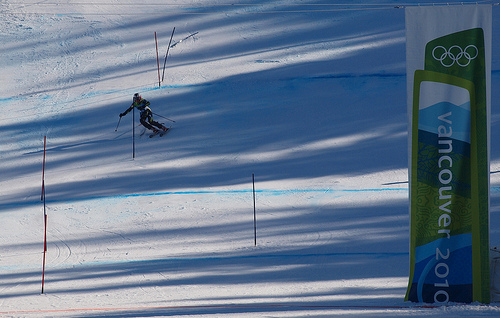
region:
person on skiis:
[117, 90, 177, 141]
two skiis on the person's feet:
[147, 124, 167, 136]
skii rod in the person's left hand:
[151, 108, 178, 130]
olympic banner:
[406, 0, 489, 308]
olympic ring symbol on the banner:
[429, 44, 481, 68]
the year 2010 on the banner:
[433, 243, 448, 303]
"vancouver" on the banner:
[438, 108, 454, 240]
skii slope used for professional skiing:
[2, 5, 403, 317]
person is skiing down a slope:
[114, 89, 176, 140]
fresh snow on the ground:
[0, 7, 497, 315]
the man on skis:
[101, 76, 183, 157]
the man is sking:
[112, 87, 214, 149]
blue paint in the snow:
[139, 182, 333, 249]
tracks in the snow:
[18, 23, 101, 135]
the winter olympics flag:
[407, 10, 493, 310]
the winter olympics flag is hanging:
[400, 10, 491, 311]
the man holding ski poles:
[84, 83, 199, 171]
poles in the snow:
[134, 20, 199, 97]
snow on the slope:
[268, 52, 353, 157]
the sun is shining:
[18, 28, 101, 83]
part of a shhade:
[273, 138, 304, 175]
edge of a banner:
[401, 225, 416, 248]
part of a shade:
[211, 208, 236, 248]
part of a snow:
[196, 275, 216, 302]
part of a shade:
[243, 241, 265, 272]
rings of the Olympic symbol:
[425, 42, 482, 70]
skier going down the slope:
[113, 76, 184, 150]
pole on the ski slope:
[245, 165, 268, 250]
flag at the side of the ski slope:
[400, 3, 498, 308]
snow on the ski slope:
[96, 211, 205, 311]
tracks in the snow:
[11, 11, 88, 74]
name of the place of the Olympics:
[427, 95, 467, 245]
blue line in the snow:
[263, 180, 360, 196]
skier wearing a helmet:
[116, 85, 191, 134]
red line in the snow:
[7, 300, 119, 316]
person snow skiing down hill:
[115, 88, 180, 165]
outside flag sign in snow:
[397, 3, 497, 310]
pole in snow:
[227, 163, 275, 254]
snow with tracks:
[2, 10, 76, 45]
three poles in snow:
[131, 23, 211, 85]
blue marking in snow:
[118, 175, 191, 205]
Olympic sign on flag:
[427, 36, 483, 71]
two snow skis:
[132, 119, 182, 149]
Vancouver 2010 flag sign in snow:
[401, 63, 496, 310]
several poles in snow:
[28, 128, 79, 286]